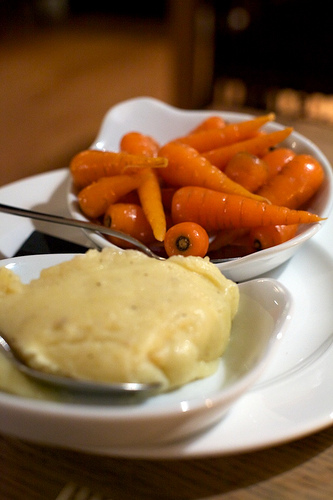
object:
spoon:
[0, 325, 160, 392]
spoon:
[0, 200, 244, 262]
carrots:
[173, 184, 330, 258]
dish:
[65, 107, 333, 269]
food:
[0, 247, 240, 407]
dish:
[0, 249, 294, 420]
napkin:
[9, 225, 104, 259]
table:
[1, 103, 331, 498]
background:
[3, 2, 327, 187]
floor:
[1, 4, 175, 179]